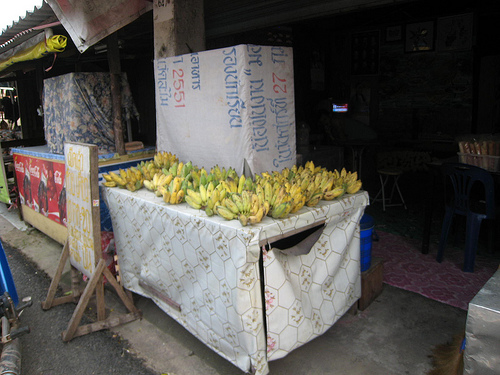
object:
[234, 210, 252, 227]
bananas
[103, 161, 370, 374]
table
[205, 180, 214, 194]
bananas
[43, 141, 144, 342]
sign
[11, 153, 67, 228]
poster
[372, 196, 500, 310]
rug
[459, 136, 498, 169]
bread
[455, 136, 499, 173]
basket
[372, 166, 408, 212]
chair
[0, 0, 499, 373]
market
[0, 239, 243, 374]
road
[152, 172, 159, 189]
banana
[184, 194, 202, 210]
banana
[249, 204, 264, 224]
banana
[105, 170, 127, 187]
banana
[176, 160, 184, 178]
banana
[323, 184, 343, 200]
banana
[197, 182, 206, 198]
banana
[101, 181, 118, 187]
banana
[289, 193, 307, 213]
banana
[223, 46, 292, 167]
font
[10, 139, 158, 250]
table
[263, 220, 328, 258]
rip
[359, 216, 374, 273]
pail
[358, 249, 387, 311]
box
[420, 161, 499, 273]
chair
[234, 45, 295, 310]
bar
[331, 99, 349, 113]
screen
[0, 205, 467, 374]
floor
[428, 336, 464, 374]
broom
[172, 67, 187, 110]
lettering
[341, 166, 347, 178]
banana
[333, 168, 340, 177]
banana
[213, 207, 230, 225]
bunch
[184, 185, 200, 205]
bunch